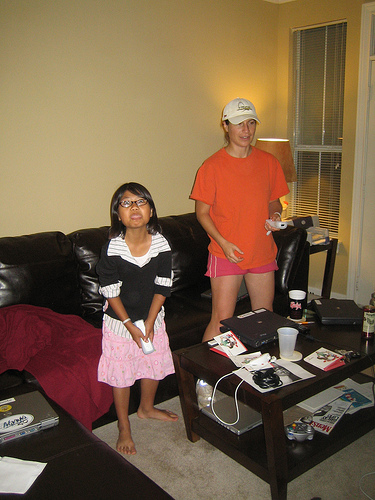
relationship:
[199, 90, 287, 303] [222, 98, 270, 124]
woman wearing hat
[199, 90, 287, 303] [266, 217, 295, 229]
woman playing wii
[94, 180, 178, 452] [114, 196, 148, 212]
girl wearing glasses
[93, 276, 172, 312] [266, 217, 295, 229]
girl playing wii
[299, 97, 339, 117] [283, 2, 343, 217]
blinds attached to window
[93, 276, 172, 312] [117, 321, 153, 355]
girl holding controller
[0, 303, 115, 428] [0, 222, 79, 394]
bedspread on top of couch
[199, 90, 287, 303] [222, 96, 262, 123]
woman wearing hat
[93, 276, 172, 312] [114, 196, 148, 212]
girl wearing glasses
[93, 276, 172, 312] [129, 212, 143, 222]
girl sticking out tongue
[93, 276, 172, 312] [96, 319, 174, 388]
girl wearing skirt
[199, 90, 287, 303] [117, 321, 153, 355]
woman holding controller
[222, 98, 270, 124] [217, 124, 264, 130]
hat on top of head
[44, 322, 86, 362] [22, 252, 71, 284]
bedspread on top of couch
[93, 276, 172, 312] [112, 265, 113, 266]
girl wearing shirt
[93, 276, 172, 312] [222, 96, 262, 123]
girl wearing hat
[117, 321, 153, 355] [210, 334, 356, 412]
controller on top of table